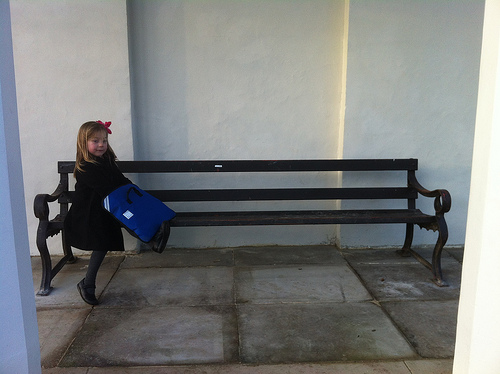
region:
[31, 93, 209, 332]
a girl is seated on a seat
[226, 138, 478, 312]
the seat is long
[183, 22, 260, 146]
the wall is white in colour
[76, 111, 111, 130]
she has a red ribbon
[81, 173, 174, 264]
she is carrying a blue bag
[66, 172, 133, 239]
her jacket is black in colour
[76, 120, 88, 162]
her hair is brown in colour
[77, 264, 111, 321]
her shoe is black in colour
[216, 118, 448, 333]
the seat is mettalic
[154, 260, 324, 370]
the floor is brown in colour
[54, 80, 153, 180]
the head of a girl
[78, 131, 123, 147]
the eyes of a girl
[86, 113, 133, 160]
the face of a girl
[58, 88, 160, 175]
the hair of a girl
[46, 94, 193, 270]
a girl with a coat on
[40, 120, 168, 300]
a girl wearing a black coat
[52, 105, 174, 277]
a black coat on a girl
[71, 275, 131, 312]
the foot of a girl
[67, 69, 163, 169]
a red bow on a girl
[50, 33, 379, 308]
a girl near a bench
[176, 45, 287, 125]
a smooth white wall.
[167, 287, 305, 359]
a dark grey side walk.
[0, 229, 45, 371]
a thick white side of the wall.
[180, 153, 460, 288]
a black metal bench.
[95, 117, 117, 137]
the little girl is wearing a red bow.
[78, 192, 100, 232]
a little girl is wearing a black coat.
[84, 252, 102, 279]
a little girl is wearing grey tights.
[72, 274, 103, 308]
a little girl is wearing black shoes.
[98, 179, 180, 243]
a little girl is holding a blue and black carry bag.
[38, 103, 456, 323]
a little girl is sitting on the black bench.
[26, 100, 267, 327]
girl with black dress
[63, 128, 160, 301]
girl with black dress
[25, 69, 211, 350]
girl sitting on the bench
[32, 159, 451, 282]
black bench for people to sit on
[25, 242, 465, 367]
ground for people to walk on/bench to sit on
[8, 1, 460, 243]
white walls to shade bench area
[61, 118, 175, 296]
little girl sitting on bench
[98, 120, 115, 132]
pink bow in little girl's hair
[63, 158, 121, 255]
long coat indicates it's cold out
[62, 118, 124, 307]
long coat, stalkings and nice shoes indicate she's going to/coming back from somewhere fancy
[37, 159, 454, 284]
bench has openings because it's outdoors and rain can just pass right through it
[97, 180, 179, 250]
little girl is holding blue item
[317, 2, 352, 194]
random sliver of light shows sun is to the left